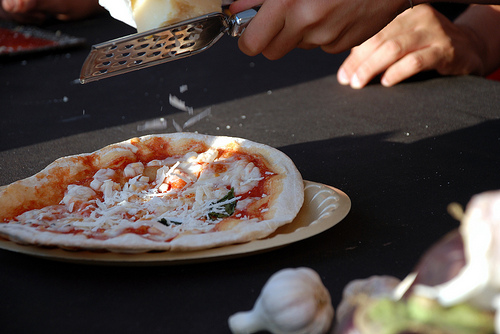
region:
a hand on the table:
[340, 14, 470, 82]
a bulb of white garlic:
[231, 270, 348, 332]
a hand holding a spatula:
[237, 0, 351, 55]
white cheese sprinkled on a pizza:
[160, 186, 202, 223]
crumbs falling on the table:
[161, 78, 226, 123]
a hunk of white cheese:
[91, 3, 227, 36]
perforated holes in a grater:
[94, 39, 175, 67]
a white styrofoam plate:
[309, 184, 343, 221]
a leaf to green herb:
[217, 190, 245, 224]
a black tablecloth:
[11, 31, 476, 323]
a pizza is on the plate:
[67, 122, 327, 331]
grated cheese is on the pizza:
[79, 133, 291, 328]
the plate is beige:
[278, 164, 382, 294]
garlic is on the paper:
[256, 272, 338, 314]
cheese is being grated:
[90, 11, 306, 128]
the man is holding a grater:
[87, 6, 348, 50]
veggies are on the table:
[358, 264, 495, 322]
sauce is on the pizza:
[27, 157, 426, 305]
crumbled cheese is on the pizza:
[62, 145, 346, 318]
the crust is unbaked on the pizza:
[58, 120, 366, 305]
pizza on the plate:
[25, 130, 347, 270]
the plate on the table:
[28, 141, 357, 273]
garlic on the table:
[246, 268, 360, 330]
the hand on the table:
[346, 30, 480, 104]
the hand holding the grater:
[229, 0, 382, 71]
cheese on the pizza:
[98, 138, 270, 255]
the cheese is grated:
[123, 165, 237, 219]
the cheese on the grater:
[57, 16, 226, 74]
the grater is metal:
[76, 7, 246, 85]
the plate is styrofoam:
[25, 140, 355, 267]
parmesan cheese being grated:
[74, 0, 260, 82]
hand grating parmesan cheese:
[62, 2, 382, 108]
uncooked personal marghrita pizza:
[2, 101, 321, 298]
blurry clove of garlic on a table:
[223, 263, 337, 332]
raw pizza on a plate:
[1, 125, 360, 264]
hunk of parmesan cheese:
[91, 0, 173, 27]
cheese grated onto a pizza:
[1, 0, 366, 282]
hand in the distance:
[329, 8, 489, 108]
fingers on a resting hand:
[332, 64, 425, 96]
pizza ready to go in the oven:
[1, 115, 366, 275]